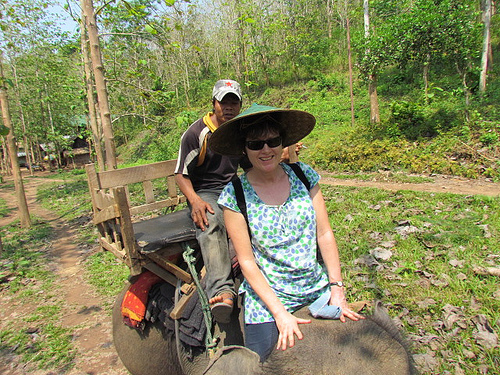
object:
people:
[209, 104, 367, 363]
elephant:
[107, 272, 417, 374]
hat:
[207, 101, 316, 159]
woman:
[206, 103, 364, 363]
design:
[255, 205, 311, 260]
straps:
[285, 163, 311, 192]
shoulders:
[171, 115, 213, 146]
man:
[173, 78, 265, 325]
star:
[225, 80, 234, 87]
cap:
[211, 78, 244, 102]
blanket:
[120, 270, 159, 332]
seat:
[83, 159, 200, 284]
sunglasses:
[244, 135, 284, 150]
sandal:
[208, 295, 235, 326]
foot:
[206, 286, 236, 325]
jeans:
[242, 315, 284, 365]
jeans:
[186, 185, 229, 296]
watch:
[326, 281, 345, 288]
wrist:
[328, 284, 346, 301]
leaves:
[394, 221, 417, 239]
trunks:
[77, 0, 120, 172]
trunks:
[348, 0, 382, 131]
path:
[0, 172, 129, 375]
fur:
[303, 329, 368, 374]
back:
[125, 257, 409, 374]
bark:
[470, 263, 499, 279]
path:
[311, 167, 500, 198]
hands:
[273, 312, 311, 351]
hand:
[187, 198, 216, 230]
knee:
[193, 205, 228, 233]